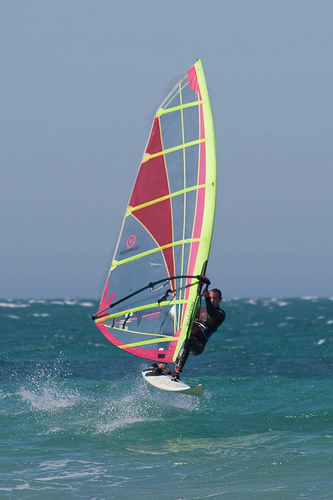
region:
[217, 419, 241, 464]
clear water on sea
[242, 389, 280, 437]
clear water on sea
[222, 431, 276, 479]
clear water on sea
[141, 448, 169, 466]
clear water on sea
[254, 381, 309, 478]
clear water on sea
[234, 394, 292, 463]
clear water on sea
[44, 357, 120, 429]
splash of clear water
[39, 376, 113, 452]
splash of clear water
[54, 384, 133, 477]
splash of clear water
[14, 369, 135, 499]
splash of clear water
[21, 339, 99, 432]
splash of clear water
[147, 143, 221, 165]
Yellow strip on sail.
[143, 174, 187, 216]
Yellow strip on sail.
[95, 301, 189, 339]
Yellow strip on sail.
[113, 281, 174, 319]
Black handle on sail.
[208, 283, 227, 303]
Man has short hair.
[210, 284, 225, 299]
Man has dark hair.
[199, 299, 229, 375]
Man wearing wet suit.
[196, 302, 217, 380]
Man's wet suit is dark in color.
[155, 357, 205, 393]
Man standing on board.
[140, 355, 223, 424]
Board is white in color.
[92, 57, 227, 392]
man is windsurfing on ocean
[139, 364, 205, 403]
the board is white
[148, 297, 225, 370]
man is wearing wet suit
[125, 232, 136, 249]
red target on sail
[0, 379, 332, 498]
closest water section is greenish blue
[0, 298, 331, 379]
water past wave is dark blue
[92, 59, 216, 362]
sail is yellow, pink, and red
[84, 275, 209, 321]
long black handles on sail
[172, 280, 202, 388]
single black pole connects to board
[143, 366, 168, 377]
foot holes on board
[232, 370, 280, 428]
clear water on sea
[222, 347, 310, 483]
clear water on sea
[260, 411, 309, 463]
clear water on sea